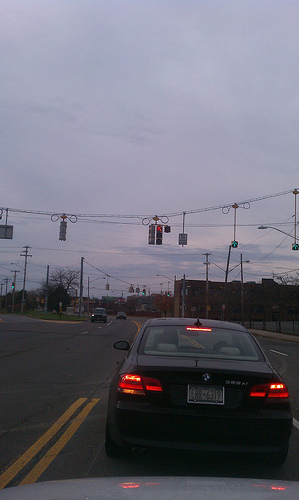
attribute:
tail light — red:
[116, 373, 161, 396]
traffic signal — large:
[142, 211, 170, 250]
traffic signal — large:
[49, 207, 77, 243]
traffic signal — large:
[220, 196, 250, 248]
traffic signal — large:
[288, 185, 298, 251]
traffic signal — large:
[139, 281, 147, 298]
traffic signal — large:
[140, 284, 146, 298]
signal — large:
[0, 221, 14, 239]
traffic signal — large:
[142, 220, 167, 250]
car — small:
[115, 311, 127, 317]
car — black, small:
[105, 317, 290, 467]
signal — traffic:
[151, 219, 164, 251]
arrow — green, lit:
[231, 239, 237, 247]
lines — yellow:
[0, 393, 86, 489]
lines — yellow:
[18, 394, 99, 485]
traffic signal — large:
[152, 222, 165, 247]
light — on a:
[118, 372, 164, 393]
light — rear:
[116, 370, 164, 401]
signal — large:
[225, 199, 242, 254]